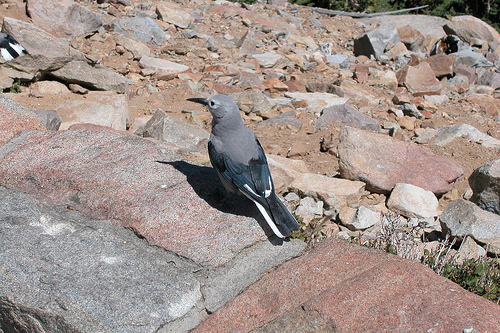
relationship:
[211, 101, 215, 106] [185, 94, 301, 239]
eye of bird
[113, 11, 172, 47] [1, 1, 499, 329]
rock on ground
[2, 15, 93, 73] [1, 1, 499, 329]
rock on ground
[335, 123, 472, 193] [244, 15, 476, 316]
rock on ground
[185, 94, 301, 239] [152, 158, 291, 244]
bird casts shadow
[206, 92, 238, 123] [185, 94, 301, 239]
head part of bird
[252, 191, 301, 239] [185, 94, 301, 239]
bird's feathers on bird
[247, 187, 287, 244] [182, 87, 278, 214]
white feathers on bird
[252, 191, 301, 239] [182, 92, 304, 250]
bird's feathers on bird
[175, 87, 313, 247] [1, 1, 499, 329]
bird standing on top of ground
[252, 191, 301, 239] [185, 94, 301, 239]
bird's feathers adorning bird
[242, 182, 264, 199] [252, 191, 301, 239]
stripe adorning bird's feathers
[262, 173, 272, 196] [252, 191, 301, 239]
stripe adorning bird's feathers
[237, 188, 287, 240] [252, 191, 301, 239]
stripe adorning bird's feathers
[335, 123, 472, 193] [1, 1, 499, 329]
rock lying on top of ground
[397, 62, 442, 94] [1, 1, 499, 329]
rock lying on top of ground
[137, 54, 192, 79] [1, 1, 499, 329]
rock lying on top of ground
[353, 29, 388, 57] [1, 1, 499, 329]
rock lying on top of ground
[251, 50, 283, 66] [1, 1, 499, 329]
rock lying on top of ground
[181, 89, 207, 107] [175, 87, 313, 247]
beak belonging to bird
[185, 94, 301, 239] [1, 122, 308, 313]
bird standing on top of rock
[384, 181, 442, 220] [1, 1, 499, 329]
rock lying on top of ground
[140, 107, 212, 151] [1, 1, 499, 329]
rock lying on top of ground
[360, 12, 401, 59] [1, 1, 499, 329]
rock lying on top of ground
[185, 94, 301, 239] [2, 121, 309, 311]
bird standing on top of brick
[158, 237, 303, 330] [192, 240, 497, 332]
grout cementing brick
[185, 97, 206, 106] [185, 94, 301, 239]
beak belonging to bird